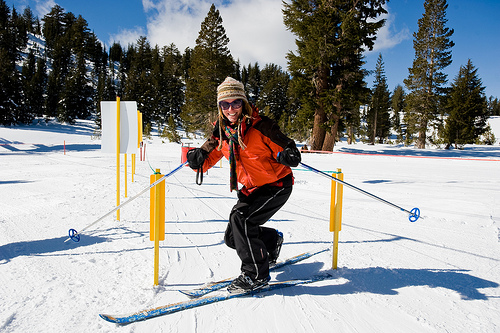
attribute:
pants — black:
[217, 170, 294, 283]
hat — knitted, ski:
[205, 69, 256, 102]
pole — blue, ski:
[299, 160, 487, 247]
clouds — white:
[227, 8, 286, 60]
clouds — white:
[367, 2, 419, 60]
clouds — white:
[174, 5, 191, 48]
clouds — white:
[141, 3, 171, 40]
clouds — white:
[29, 3, 69, 16]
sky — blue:
[6, 2, 493, 111]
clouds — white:
[238, 17, 282, 53]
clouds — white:
[231, 16, 275, 49]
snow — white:
[19, 158, 448, 297]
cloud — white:
[97, 3, 409, 83]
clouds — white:
[142, 2, 206, 49]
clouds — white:
[222, 1, 297, 66]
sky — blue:
[447, 0, 497, 62]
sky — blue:
[387, 3, 416, 71]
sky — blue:
[72, 2, 142, 29]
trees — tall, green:
[0, 0, 499, 152]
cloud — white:
[139, 2, 208, 46]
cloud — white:
[220, 10, 287, 67]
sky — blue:
[47, 3, 493, 59]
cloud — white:
[378, 5, 405, 54]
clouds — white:
[213, 7, 424, 75]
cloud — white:
[17, 1, 107, 52]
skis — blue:
[132, 262, 310, 320]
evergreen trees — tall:
[1, 0, 498, 156]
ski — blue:
[98, 269, 336, 324]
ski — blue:
[179, 247, 329, 297]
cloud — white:
[108, 2, 410, 72]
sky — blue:
[4, 0, 484, 91]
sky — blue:
[394, 11, 484, 89]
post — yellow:
[146, 172, 169, 279]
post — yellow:
[328, 169, 344, 273]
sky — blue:
[397, 3, 485, 78]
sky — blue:
[393, 1, 485, 73]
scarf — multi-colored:
[215, 117, 249, 188]